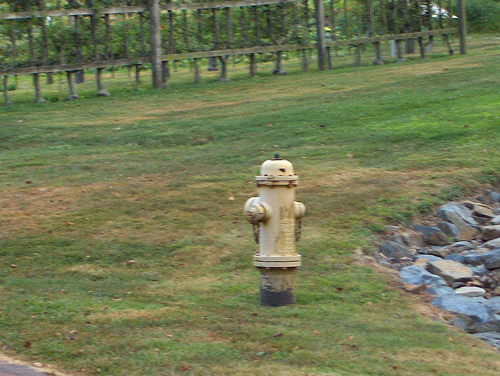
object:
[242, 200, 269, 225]
cap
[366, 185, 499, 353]
rock bed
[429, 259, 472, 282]
rock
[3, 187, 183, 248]
brown grass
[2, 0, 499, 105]
background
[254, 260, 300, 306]
bottom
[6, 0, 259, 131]
bushes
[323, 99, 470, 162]
lawn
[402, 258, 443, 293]
rock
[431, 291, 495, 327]
rock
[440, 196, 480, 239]
rock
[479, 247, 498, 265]
rock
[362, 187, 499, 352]
ditch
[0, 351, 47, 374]
asphalt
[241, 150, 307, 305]
fire hydrant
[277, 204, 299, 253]
lettering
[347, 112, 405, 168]
photo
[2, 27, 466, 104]
fence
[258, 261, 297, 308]
base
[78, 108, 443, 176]
grass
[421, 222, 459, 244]
rocks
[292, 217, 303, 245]
chain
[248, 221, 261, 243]
chain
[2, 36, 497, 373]
ground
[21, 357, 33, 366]
portion